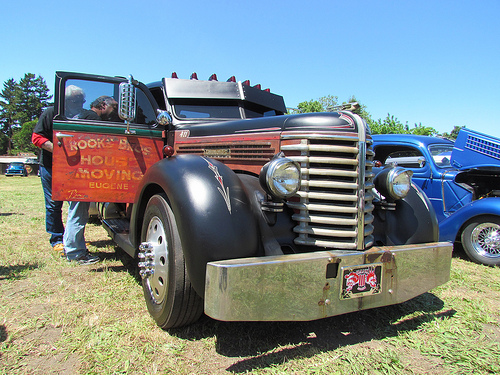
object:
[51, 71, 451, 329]
vehicle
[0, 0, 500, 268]
background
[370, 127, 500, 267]
truck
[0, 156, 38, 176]
building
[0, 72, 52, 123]
tree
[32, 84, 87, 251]
man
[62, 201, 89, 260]
jeans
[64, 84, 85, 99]
hair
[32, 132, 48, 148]
shirt sleeve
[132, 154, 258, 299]
wheel hub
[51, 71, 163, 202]
door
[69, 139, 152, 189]
business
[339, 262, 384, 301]
license plate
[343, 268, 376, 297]
design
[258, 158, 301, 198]
headlight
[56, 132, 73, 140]
door handle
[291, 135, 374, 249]
front grill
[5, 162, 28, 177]
car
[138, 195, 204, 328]
tire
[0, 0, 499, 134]
sky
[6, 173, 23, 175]
bumper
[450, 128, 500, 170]
hood up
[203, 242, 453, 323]
fender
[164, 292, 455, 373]
shadow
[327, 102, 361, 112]
ornament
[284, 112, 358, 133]
hood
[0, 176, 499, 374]
field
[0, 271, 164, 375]
grass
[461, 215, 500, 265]
wheel